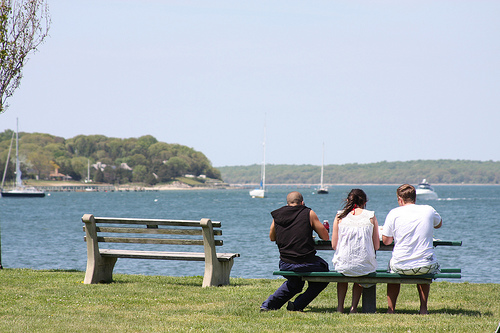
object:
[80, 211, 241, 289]
bench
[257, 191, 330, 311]
man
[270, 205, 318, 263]
black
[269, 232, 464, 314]
table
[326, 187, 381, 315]
lady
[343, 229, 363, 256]
white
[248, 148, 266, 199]
sailboat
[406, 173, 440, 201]
motorboat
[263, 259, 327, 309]
pants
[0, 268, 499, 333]
grass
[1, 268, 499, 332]
bank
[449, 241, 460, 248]
green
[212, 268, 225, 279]
gray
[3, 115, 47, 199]
boat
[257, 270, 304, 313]
leg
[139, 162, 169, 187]
section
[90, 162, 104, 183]
trees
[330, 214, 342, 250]
arm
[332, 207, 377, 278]
shirt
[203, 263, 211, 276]
cement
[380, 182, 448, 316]
people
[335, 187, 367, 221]
hair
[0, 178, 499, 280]
water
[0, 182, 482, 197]
harbor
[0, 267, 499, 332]
ground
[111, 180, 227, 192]
shoreline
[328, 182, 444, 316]
friends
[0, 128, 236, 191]
land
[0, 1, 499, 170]
sky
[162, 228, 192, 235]
wooden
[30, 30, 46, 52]
branches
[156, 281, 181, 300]
short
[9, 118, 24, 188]
mast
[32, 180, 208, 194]
dock